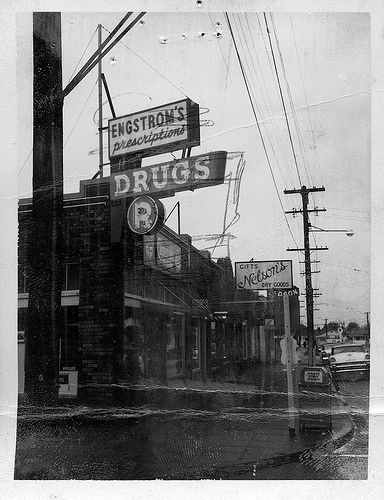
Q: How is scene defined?
A: Old.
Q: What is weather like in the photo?
A: Rainy.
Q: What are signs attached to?
A: Building.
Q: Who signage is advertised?
A: Engstrom.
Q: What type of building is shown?
A: Brick.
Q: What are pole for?
A: Power lines.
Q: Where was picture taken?
A: On a street corner.